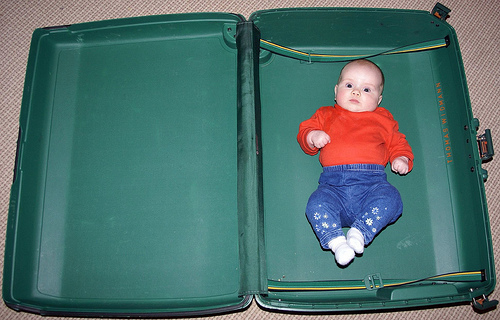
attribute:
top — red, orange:
[297, 108, 423, 162]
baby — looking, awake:
[302, 57, 405, 253]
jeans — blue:
[303, 167, 402, 264]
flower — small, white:
[366, 216, 374, 224]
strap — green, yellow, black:
[257, 31, 449, 63]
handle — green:
[482, 129, 496, 157]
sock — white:
[327, 235, 355, 267]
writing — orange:
[435, 78, 456, 166]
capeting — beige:
[1, 2, 499, 318]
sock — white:
[349, 229, 367, 253]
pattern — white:
[313, 202, 381, 238]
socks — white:
[340, 238, 358, 266]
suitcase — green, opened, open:
[24, 21, 482, 286]